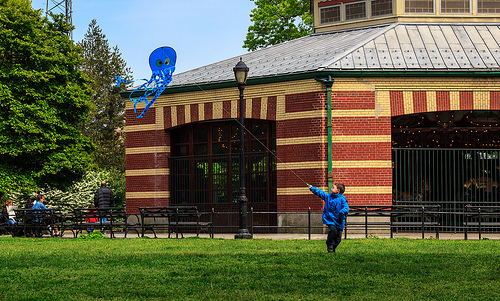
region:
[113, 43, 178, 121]
a kite shaped like an octopus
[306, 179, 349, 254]
a kid flying a kite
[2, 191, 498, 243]
a row of benches facing the building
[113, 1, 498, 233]
a red and yellow brick building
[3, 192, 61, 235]
people sitting on the far left bench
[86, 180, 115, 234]
an adult walking with a child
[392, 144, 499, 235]
a green fence in front of the building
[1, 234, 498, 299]
a grassy field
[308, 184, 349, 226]
a bright blue jacket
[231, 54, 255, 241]
a lamppost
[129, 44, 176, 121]
a blue octopus kite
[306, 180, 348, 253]
a boy flying a kite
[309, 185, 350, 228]
a blue jacket on a boy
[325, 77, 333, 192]
a green drain pipe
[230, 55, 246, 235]
a black lampost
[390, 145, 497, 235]
an black iron fence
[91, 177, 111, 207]
a man in a black jacket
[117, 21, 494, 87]
a roof on a building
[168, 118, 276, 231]
wood framed windows in a wall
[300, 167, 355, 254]
boy flying a kite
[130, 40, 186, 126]
blue kite flying in the air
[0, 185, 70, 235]
people sitting on park benches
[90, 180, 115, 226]
person with a black coat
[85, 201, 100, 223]
child with red coat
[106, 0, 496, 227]
carosel in park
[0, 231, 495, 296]
green grass in park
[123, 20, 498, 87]
shingles on roof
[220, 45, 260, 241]
tall black lamp post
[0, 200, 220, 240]
black park benches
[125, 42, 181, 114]
The kite is an octopus.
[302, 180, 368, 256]
The boy is running in the yard.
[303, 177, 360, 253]
The boy is a young boy.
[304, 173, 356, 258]
The boy is wearing a blue sweater.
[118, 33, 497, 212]
The boy is in the park.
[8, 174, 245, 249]
People are sitting on the benches.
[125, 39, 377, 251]
The boy is running with the kite.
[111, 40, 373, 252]
The young boy is running fast.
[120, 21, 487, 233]
There is a fence around the pavillion.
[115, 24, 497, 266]
The boy is alone in the park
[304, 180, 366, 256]
young boy running across the grass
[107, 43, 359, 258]
young boy flying a kite in the park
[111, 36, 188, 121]
the kite the young boy is flying is blue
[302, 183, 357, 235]
the young boy is wearing a blue sweatshirt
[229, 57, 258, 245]
Lamp post infront of fence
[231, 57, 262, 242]
the lamppost not far from the benches is black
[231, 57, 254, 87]
the light at the top of the lamp post is not lite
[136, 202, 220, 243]
the black bench on the other side of the fence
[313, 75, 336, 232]
the gutter attached to the round house is green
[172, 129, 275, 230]
the openings is closed with an iron gate that is black